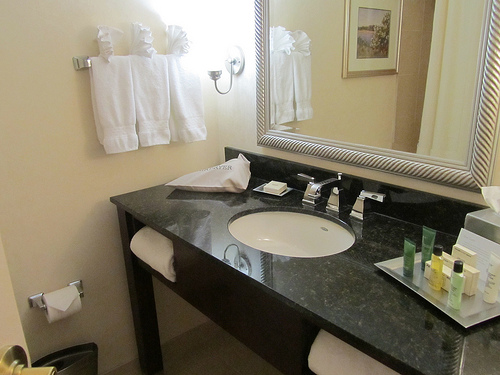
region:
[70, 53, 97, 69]
portion of silver bathroom towel rack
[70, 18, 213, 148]
towel rack with white towels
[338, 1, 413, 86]
image in mirror of square picture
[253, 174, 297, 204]
white bar soap in square dish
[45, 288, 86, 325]
toilet paper folded in triangle pattern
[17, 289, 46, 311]
portion of silver toilet paper holder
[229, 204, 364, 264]
white round bathroom sink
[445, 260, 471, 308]
green bottle with black lid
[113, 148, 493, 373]
black shiny vanity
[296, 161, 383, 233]
silver shiny faucets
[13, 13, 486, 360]
A clean, modern bath room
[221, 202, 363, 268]
Oval sink with in marble surface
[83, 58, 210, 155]
Three towels hanging on a rack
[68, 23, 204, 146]
Six towels arranged on a rack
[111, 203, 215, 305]
A towel compartment in a bathroom counter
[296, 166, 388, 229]
Fixtures on a bathroom counter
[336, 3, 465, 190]
A picture reflected in a mirror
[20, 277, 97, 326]
A roll of toilet paper on a holder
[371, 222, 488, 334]
An assortment of toiletries on the counter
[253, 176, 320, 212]
A bar of soap near a sink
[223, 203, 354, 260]
a white sink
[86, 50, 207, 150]
three hanging white towels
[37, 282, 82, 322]
a roll of toilet paper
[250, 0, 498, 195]
a big framed mirror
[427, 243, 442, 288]
a small yellow bottle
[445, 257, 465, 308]
a small green bottle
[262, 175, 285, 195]
a bar of soap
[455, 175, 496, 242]
a box of tissues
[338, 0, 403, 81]
a reflection of a painting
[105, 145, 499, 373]
a shiny marble countertop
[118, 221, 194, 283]
towel holder with white towel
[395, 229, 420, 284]
upright green tube on counter top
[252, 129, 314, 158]
decorative edge of bathroom mirror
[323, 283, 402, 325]
portion of black marble counter top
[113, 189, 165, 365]
leg of black marble counter top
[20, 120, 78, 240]
portion of tan bathroom wall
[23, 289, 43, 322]
silver metal toilet paper holder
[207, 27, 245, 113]
white bathroom bulb holder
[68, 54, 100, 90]
portion of white towel holder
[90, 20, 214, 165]
three decorative white towels on towel rack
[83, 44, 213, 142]
three towels hanging up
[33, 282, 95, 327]
folded toilet paper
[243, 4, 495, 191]
a mirror on the wall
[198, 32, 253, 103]
a bright light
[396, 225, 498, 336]
a tray of necessities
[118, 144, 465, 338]
black bathroom counter top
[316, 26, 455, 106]
reflection of picture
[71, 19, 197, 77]
three fan shapes things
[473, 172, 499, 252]
a box of tissue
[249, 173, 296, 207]
a bar of soap